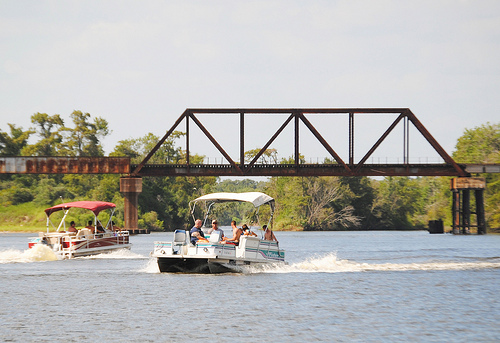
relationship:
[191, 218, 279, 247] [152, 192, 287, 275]
passengers on a pontoon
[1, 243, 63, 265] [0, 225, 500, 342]
wake in water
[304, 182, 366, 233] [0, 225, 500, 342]
tree in river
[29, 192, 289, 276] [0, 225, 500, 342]
boating in water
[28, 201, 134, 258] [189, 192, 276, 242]
boat has canopy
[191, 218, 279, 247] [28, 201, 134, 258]
men on boat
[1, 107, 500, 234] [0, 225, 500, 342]
bridge above water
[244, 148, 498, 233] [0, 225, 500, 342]
island in water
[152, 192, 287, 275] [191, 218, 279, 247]
pontoon full of men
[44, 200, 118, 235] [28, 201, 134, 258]
canopy on pontoon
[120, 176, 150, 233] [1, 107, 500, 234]
pillar on bridge